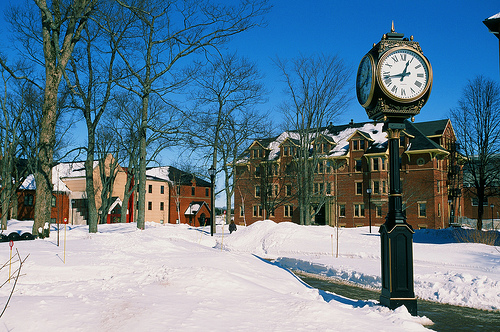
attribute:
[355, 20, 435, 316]
clock — green, gold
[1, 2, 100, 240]
tree — brown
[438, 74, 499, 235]
tree — brown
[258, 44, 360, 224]
tree — brown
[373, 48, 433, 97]
clock — green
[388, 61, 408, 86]
face — white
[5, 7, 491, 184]
sky — clear, blue, patch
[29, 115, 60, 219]
tree trunk — dark brown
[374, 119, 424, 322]
pole — dark black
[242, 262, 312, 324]
snow — clean, white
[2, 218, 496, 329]
ground — snow-covered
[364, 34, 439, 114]
clock — front face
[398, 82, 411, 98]
numerals — roman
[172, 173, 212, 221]
building — red brick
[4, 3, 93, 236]
tree — BARE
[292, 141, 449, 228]
walls — brick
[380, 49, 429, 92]
numerals — roman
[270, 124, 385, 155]
snow — on roof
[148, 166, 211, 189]
roof — black